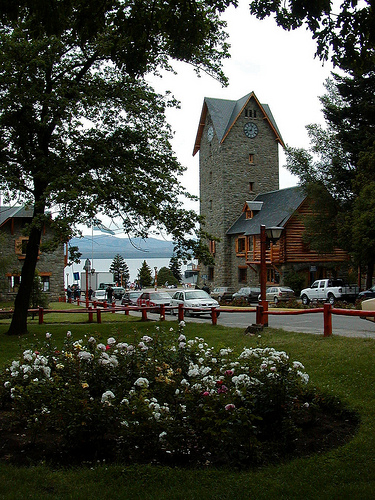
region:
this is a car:
[166, 286, 219, 317]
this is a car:
[131, 286, 174, 313]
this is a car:
[253, 280, 294, 299]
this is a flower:
[132, 373, 149, 395]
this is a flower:
[98, 388, 120, 402]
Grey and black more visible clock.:
[243, 121, 259, 139]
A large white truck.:
[299, 278, 359, 306]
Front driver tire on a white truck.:
[301, 293, 308, 306]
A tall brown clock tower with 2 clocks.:
[191, 90, 289, 290]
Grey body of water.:
[64, 257, 196, 285]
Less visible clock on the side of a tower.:
[205, 125, 214, 143]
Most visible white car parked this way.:
[168, 289, 219, 316]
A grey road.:
[217, 308, 374, 332]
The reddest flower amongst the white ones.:
[105, 342, 111, 350]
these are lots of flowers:
[126, 364, 263, 441]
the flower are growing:
[18, 344, 260, 458]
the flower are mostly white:
[70, 333, 271, 440]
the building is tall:
[187, 107, 324, 254]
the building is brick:
[216, 112, 304, 239]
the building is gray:
[198, 88, 323, 285]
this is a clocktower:
[178, 84, 295, 193]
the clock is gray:
[232, 105, 279, 161]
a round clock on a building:
[243, 122, 263, 137]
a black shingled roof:
[257, 181, 306, 243]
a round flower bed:
[0, 333, 360, 478]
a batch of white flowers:
[233, 345, 321, 388]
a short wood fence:
[35, 302, 188, 328]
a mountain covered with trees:
[79, 229, 173, 258]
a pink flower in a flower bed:
[220, 398, 239, 413]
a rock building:
[198, 140, 237, 294]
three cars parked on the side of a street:
[118, 287, 216, 312]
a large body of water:
[82, 249, 168, 280]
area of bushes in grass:
[1, 318, 322, 468]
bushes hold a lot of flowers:
[0, 317, 324, 475]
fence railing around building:
[2, 295, 186, 326]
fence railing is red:
[1, 293, 187, 332]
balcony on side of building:
[242, 243, 281, 265]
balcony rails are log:
[242, 244, 281, 268]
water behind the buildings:
[64, 252, 200, 299]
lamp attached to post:
[262, 223, 282, 244]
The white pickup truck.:
[300, 278, 361, 304]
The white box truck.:
[80, 270, 115, 290]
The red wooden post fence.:
[21, 294, 372, 339]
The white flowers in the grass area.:
[8, 338, 343, 452]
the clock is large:
[244, 122, 258, 138]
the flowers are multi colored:
[1, 318, 320, 470]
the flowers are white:
[1, 313, 312, 463]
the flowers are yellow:
[2, 319, 314, 465]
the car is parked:
[170, 287, 221, 317]